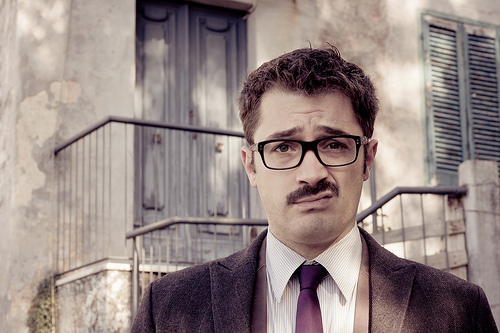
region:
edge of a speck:
[268, 130, 297, 143]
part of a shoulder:
[451, 277, 479, 303]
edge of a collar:
[335, 282, 351, 307]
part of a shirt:
[323, 298, 335, 315]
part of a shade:
[326, 289, 350, 318]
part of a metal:
[115, 207, 162, 244]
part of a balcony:
[133, 151, 183, 206]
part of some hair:
[348, 70, 374, 109]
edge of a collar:
[332, 280, 348, 296]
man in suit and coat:
[191, 46, 461, 327]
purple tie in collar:
[277, 253, 334, 326]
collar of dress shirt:
[262, 245, 361, 302]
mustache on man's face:
[280, 176, 343, 216]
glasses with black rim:
[248, 125, 370, 177]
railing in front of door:
[87, 118, 225, 271]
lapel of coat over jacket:
[212, 261, 260, 329]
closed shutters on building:
[416, 13, 498, 173]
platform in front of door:
[70, 243, 182, 290]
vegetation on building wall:
[22, 270, 59, 331]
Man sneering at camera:
[210, 60, 484, 285]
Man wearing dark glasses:
[255, 132, 373, 184]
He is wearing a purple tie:
[273, 250, 348, 322]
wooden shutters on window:
[422, 7, 489, 178]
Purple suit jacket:
[160, 269, 471, 331]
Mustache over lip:
[283, 188, 372, 217]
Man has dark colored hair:
[221, 47, 406, 131]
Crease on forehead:
[295, 105, 345, 138]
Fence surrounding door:
[43, 110, 248, 272]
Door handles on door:
[145, 99, 235, 179]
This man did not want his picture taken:
[7, 8, 491, 320]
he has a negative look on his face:
[185, 19, 423, 302]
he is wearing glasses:
[228, 92, 400, 247]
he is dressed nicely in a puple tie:
[136, 202, 498, 331]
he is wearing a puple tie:
[265, 226, 362, 331]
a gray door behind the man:
[121, 7, 273, 276]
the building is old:
[35, 5, 485, 243]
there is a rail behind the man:
[43, 105, 478, 283]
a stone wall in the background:
[270, 2, 492, 284]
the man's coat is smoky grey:
[134, 217, 491, 331]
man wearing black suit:
[219, 305, 231, 316]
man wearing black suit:
[224, 300, 240, 311]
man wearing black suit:
[257, 294, 267, 311]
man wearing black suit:
[204, 286, 221, 310]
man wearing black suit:
[207, 303, 224, 326]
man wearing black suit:
[232, 295, 244, 309]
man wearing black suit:
[194, 315, 210, 325]